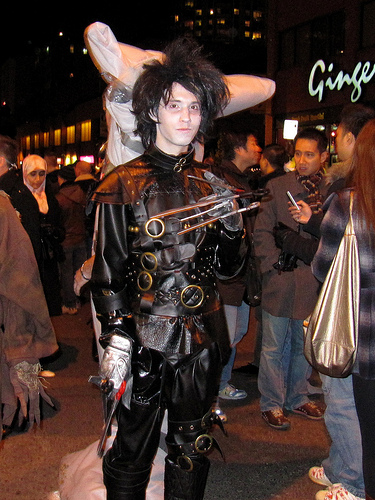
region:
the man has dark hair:
[71, 18, 306, 195]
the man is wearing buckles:
[155, 410, 234, 496]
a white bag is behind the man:
[69, 429, 162, 492]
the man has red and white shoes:
[306, 457, 335, 491]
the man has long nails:
[11, 368, 101, 445]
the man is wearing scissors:
[170, 189, 362, 306]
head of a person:
[134, 60, 231, 148]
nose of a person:
[179, 115, 201, 126]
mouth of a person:
[174, 126, 197, 144]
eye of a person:
[160, 86, 183, 117]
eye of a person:
[189, 97, 201, 118]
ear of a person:
[150, 91, 159, 136]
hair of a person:
[156, 50, 206, 86]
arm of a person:
[86, 173, 133, 318]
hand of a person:
[85, 345, 138, 398]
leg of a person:
[92, 401, 167, 492]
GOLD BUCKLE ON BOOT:
[194, 434, 207, 458]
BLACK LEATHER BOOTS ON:
[119, 426, 139, 487]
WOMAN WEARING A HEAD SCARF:
[29, 156, 42, 170]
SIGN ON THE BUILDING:
[306, 57, 371, 107]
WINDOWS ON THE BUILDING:
[78, 122, 94, 142]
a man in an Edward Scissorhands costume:
[79, 33, 264, 499]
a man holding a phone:
[282, 187, 307, 213]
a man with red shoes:
[256, 388, 325, 431]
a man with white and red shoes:
[302, 460, 360, 498]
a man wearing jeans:
[257, 282, 312, 412]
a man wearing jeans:
[318, 301, 366, 499]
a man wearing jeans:
[207, 284, 249, 392]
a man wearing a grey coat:
[252, 163, 339, 319]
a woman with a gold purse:
[301, 184, 362, 378]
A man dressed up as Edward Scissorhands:
[82, 27, 278, 496]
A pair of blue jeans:
[248, 300, 317, 412]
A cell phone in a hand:
[279, 181, 311, 226]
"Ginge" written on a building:
[296, 48, 371, 104]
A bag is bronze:
[294, 182, 363, 383]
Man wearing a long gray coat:
[244, 120, 334, 323]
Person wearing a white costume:
[70, 12, 282, 180]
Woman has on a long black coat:
[2, 140, 70, 320]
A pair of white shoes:
[301, 457, 370, 497]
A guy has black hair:
[285, 120, 332, 175]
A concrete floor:
[17, 281, 359, 489]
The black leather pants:
[98, 348, 235, 499]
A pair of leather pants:
[100, 340, 235, 497]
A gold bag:
[285, 235, 368, 380]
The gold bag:
[297, 233, 360, 384]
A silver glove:
[77, 325, 157, 411]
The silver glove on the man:
[84, 323, 144, 398]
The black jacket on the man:
[87, 228, 242, 360]